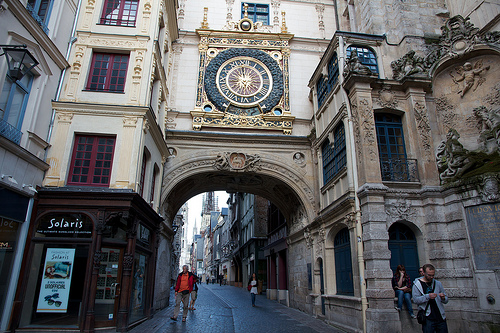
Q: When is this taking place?
A: Daytime.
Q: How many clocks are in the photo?
A: One.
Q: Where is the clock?
A: On the front of the building.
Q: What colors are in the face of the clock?
A: Gold and green.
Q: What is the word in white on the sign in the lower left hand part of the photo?
A: Solaris.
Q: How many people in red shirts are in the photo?
A: One.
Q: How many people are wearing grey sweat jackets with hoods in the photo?
A: One.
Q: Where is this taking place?
A: In a city.